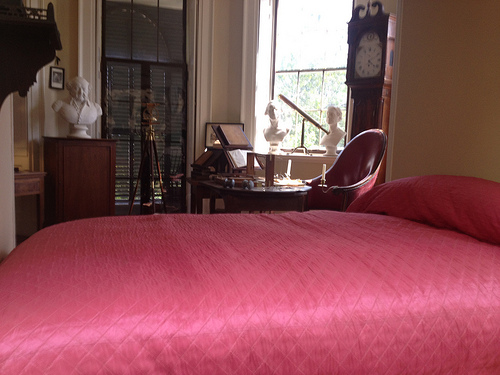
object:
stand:
[36, 136, 124, 228]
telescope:
[127, 100, 169, 216]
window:
[254, 0, 354, 147]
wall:
[403, 29, 480, 143]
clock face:
[348, 33, 393, 92]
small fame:
[51, 65, 67, 89]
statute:
[262, 98, 291, 150]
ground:
[203, 194, 228, 215]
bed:
[0, 173, 500, 374]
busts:
[257, 97, 297, 154]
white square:
[354, 41, 381, 76]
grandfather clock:
[343, 0, 398, 187]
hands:
[370, 61, 377, 68]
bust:
[316, 103, 346, 155]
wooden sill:
[258, 151, 334, 163]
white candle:
[322, 162, 328, 179]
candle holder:
[318, 160, 328, 186]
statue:
[316, 98, 343, 158]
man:
[48, 73, 106, 138]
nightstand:
[15, 171, 49, 237]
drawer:
[13, 173, 49, 198]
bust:
[58, 75, 107, 141]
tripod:
[124, 107, 170, 207]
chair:
[303, 127, 391, 209]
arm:
[324, 175, 369, 196]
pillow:
[344, 165, 496, 243]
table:
[196, 171, 321, 210]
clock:
[347, 27, 393, 91]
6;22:
[365, 56, 381, 75]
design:
[52, 220, 239, 310]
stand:
[12, 165, 46, 245]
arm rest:
[322, 172, 373, 211]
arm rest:
[297, 164, 333, 184]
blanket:
[0, 204, 475, 368]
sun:
[255, 0, 344, 150]